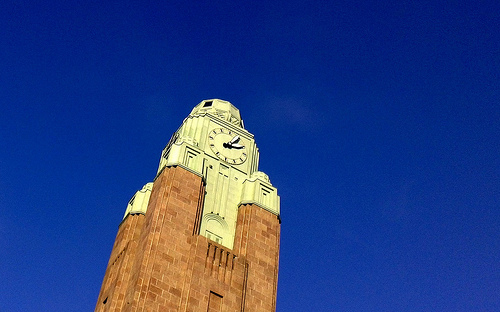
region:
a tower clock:
[91, 92, 325, 309]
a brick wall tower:
[93, 165, 308, 310]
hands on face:
[209, 125, 256, 164]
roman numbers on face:
[202, 122, 251, 167]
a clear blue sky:
[5, 6, 499, 311]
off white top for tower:
[122, 90, 280, 245]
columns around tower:
[117, 144, 282, 214]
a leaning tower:
[89, 91, 284, 311]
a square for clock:
[197, 110, 257, 177]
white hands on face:
[224, 130, 244, 152]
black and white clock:
[208, 116, 244, 174]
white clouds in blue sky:
[23, 17, 76, 61]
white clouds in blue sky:
[41, 84, 83, 131]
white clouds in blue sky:
[89, 84, 142, 128]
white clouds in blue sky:
[33, 114, 101, 201]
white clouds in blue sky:
[6, 178, 48, 222]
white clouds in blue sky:
[23, 225, 78, 259]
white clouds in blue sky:
[103, 30, 158, 66]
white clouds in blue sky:
[185, 33, 234, 63]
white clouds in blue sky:
[263, 71, 345, 124]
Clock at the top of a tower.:
[207, 127, 249, 163]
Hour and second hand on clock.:
[222, 134, 244, 149]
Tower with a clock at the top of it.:
[93, 96, 280, 308]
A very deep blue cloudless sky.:
[1, 1, 498, 310]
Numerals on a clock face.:
[208, 125, 249, 163]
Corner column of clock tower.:
[234, 168, 281, 310]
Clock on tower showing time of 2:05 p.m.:
[203, 113, 249, 176]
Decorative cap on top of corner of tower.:
[237, 169, 280, 215]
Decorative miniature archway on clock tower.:
[196, 211, 234, 248]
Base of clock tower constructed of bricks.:
[93, 163, 278, 310]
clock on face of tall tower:
[201, 121, 251, 169]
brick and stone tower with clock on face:
[88, 93, 289, 308]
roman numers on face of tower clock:
[206, 123, 251, 169]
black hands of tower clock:
[224, 135, 246, 150]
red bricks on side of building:
[141, 267, 180, 299]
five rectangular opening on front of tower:
[198, 233, 243, 272]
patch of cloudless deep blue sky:
[288, 63, 498, 293]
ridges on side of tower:
[177, 110, 207, 147]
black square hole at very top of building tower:
[201, 98, 216, 112]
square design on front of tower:
[255, 178, 275, 210]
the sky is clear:
[281, 57, 357, 209]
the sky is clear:
[363, 157, 449, 264]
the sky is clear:
[44, 89, 115, 219]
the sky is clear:
[74, 39, 298, 132]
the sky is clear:
[307, 107, 401, 252]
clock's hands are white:
[202, 109, 269, 203]